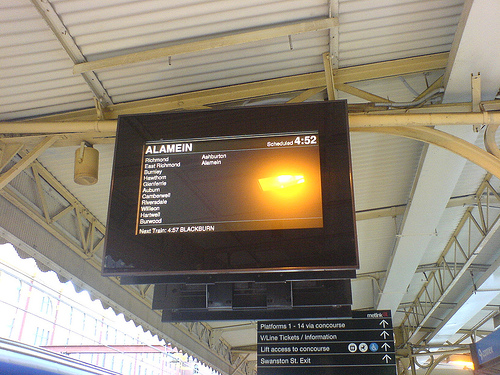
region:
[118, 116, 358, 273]
this is a television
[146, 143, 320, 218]
this is the screen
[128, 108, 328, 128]
the frame is black in color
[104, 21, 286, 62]
this is the roof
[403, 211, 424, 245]
the roof is white in color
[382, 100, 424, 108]
this is a pipe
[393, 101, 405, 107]
the pipe is white in color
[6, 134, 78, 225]
this is a metal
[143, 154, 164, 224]
these are the writing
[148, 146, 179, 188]
the writings are in white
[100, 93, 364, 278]
a black television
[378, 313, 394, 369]
white arrows on the sign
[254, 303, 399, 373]
a black direction sign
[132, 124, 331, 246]
a lit television screen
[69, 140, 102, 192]
a yellow light fixture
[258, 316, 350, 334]
white letters on the sign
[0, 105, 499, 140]
a yellow metal bar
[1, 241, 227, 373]
windows in the building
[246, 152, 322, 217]
a light shining on the screen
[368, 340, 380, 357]
a blue handicapped logo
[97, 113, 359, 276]
a travel marquee at the train station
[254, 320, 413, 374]
a directional sign on the platform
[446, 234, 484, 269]
white metal ceiling supports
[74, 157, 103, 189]
a white tubular light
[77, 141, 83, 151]
metal mount on the light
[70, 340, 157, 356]
a red metal beam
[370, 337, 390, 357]
a blue handicap sticker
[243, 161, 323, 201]
light reflecting off the monitor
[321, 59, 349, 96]
white metal mounts supporting the marquee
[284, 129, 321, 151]
digital time displayed on the screen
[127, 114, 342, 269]
Screen showing train schedule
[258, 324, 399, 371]
Signage for directions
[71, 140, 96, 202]
a light fixture that is not turned on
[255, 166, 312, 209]
reflection on a light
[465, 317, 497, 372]
a sign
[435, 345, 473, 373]
a powered on light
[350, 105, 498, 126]
a pipe for the building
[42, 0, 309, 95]
Corrugated steel cieling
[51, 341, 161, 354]
a metal girder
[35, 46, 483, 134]
Support beam for the roof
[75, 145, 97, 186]
yellow can light is hanging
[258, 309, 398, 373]
black sign hanging from ceiling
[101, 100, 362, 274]
display board is hanging from ceiling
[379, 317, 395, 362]
four white arrows on sign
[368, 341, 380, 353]
blue circle on sign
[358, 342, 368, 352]
white circle on sign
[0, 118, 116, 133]
yellow pipe behind display board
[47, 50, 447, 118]
yellow metal beam on ceiling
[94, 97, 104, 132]
bracket holding pipe to ceiling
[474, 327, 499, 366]
blue sign to the right of hanging sign